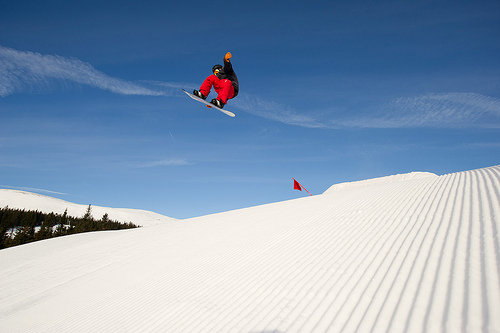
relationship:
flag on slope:
[292, 178, 304, 192] [0, 164, 497, 331]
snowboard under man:
[181, 88, 234, 119] [194, 50, 239, 110]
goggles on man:
[211, 68, 219, 75] [185, 52, 239, 108]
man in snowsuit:
[185, 52, 239, 108] [189, 61, 249, 100]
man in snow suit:
[185, 52, 239, 108] [198, 61, 239, 105]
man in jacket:
[185, 52, 239, 108] [212, 56, 239, 99]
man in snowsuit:
[185, 52, 239, 108] [189, 57, 240, 104]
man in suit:
[185, 59, 363, 140] [195, 57, 282, 128]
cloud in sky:
[1, 45, 498, 130] [2, 1, 499, 219]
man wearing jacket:
[185, 52, 239, 108] [212, 62, 237, 92]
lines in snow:
[436, 178, 491, 325] [9, 188, 493, 324]